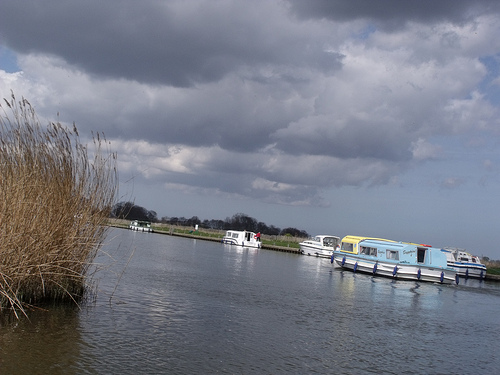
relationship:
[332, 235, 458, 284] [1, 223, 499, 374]
boat reflecting on water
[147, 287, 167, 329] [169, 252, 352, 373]
light hitting water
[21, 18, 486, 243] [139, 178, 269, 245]
sky above land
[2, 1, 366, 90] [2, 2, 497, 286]
cloud in sky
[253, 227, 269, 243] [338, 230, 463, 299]
person on boat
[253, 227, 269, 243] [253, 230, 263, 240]
person wearing jacket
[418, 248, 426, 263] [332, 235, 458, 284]
door in back of a boat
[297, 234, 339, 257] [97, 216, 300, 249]
boat near shore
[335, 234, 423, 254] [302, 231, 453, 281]
roof on front of boat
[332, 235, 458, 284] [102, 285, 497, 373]
boat on water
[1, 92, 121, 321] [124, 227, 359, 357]
reeds in water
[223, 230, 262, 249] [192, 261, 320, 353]
boat on water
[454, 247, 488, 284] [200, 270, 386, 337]
boat on water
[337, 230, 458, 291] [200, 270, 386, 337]
boat on water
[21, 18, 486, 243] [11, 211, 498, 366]
sky above water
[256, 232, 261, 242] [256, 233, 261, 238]
person wearing jacket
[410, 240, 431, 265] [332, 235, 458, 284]
door on boat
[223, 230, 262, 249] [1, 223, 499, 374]
boat on water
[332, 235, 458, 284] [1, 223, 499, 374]
boat on water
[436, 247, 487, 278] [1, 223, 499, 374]
boat on water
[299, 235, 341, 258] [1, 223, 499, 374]
boat on water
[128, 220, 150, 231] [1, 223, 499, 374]
boats on water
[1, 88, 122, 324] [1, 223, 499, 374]
reeds growing along water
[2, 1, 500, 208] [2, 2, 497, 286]
cloud in sky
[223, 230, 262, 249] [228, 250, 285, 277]
boat in water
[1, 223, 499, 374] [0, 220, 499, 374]
water in waterway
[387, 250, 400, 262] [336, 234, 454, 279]
window on boat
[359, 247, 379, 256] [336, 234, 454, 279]
window on boat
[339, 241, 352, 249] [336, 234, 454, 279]
window on boat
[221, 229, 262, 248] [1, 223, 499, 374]
boat in water